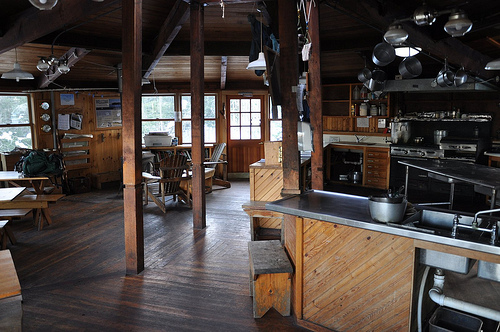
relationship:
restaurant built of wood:
[3, 3, 497, 328] [17, 79, 399, 329]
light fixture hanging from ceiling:
[390, 38, 426, 64] [319, 2, 497, 58]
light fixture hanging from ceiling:
[379, 4, 479, 47] [319, 2, 497, 58]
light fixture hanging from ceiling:
[0, 50, 37, 86] [0, 1, 126, 83]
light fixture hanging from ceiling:
[33, 47, 75, 84] [0, 1, 126, 83]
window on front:
[0, 94, 35, 154] [0, 89, 287, 190]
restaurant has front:
[3, 3, 497, 328] [0, 89, 287, 190]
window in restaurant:
[0, 94, 35, 154] [3, 3, 497, 328]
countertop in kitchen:
[261, 186, 421, 231] [264, 0, 494, 329]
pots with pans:
[355, 22, 417, 65] [342, 57, 447, 131]